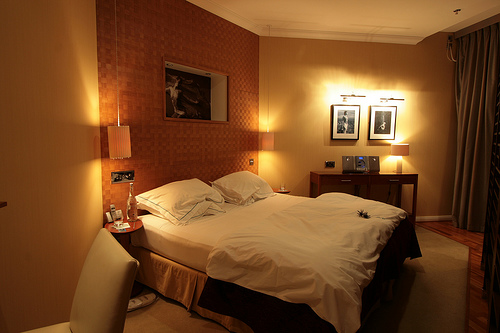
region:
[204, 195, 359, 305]
this is the bed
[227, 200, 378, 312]
the bed is well spread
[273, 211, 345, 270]
the sheet is white in collor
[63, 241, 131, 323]
this is the chair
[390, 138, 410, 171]
this is the light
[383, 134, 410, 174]
the light is on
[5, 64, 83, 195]
this is the wall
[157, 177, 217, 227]
this is the pillow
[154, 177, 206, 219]
the pillow is white in color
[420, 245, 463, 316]
this is the floor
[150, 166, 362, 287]
Cot is in center of the room.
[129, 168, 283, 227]
Pillow are white color.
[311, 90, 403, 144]
Pictures are hanging in wall.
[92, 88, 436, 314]
Lights are on.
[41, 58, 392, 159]
wall is brown color.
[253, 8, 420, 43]
Ceiling is white color.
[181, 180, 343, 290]
Bed sheet is white color.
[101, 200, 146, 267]
Side table is brown color.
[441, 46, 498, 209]
Curtain is brown color.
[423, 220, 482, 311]
Carpet is in floor.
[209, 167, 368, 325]
this is a bed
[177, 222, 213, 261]
this is the mattress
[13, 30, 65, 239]
this is the wall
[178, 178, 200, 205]
this is a pillow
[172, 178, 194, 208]
the pillow is white in color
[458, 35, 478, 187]
this is curtain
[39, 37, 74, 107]
the wall is cream in color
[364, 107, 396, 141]
this is a picture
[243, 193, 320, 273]
this is a blanket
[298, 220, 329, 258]
the blanket is white in color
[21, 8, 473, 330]
the scene is in a bedroom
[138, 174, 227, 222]
the pillows are white in colour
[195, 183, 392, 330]
the sheets are white in colour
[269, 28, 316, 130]
the wall is brown in colour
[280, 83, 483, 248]
the lights are on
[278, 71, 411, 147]
pictures are on the wall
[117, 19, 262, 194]
the wall is brown in colour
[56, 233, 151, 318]
the seat is white incolour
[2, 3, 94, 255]
the door is closed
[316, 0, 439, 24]
the roof is white in colour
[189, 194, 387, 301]
this is a bed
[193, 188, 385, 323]
the bed is big in size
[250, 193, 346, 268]
the sheet is white in color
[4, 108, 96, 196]
the wall is cream in color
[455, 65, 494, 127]
this is the curtain